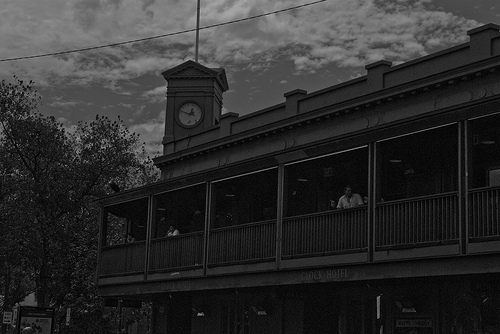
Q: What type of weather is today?
A: It is cloudy.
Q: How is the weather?
A: It is cloudy.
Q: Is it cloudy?
A: Yes, it is cloudy.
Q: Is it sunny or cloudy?
A: It is cloudy.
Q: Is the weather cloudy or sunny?
A: It is cloudy.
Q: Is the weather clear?
A: No, it is cloudy.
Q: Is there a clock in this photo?
A: Yes, there is a clock.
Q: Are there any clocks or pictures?
A: Yes, there is a clock.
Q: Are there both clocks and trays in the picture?
A: No, there is a clock but no trays.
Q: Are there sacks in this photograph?
A: No, there are no sacks.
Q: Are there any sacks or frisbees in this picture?
A: No, there are no sacks or frisbees.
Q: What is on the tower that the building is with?
A: The clock is on the tower.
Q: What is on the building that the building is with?
A: The clock is on the tower.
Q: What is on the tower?
A: The clock is on the tower.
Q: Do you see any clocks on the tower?
A: Yes, there is a clock on the tower.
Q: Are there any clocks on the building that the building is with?
A: Yes, there is a clock on the tower.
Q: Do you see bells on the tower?
A: No, there is a clock on the tower.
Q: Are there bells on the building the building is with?
A: No, there is a clock on the tower.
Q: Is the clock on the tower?
A: Yes, the clock is on the tower.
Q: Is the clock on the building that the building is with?
A: Yes, the clock is on the tower.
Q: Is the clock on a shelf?
A: No, the clock is on the tower.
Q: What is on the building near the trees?
A: The clock is on the building.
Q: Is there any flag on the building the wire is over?
A: No, there is a clock on the building.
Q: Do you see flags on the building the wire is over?
A: No, there is a clock on the building.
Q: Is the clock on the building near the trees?
A: Yes, the clock is on the building.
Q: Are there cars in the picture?
A: No, there are no cars.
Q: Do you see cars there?
A: No, there are no cars.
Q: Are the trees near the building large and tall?
A: Yes, the trees are large and tall.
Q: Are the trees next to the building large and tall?
A: Yes, the trees are large and tall.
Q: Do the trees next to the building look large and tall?
A: Yes, the trees are large and tall.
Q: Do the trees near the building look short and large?
A: No, the trees are large but tall.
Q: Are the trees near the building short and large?
A: No, the trees are large but tall.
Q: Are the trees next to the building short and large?
A: No, the trees are large but tall.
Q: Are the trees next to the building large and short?
A: No, the trees are large but tall.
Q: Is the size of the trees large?
A: Yes, the trees are large.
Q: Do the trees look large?
A: Yes, the trees are large.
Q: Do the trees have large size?
A: Yes, the trees are large.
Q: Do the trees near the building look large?
A: Yes, the trees are large.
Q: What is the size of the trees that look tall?
A: The trees are large.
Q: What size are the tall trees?
A: The trees are large.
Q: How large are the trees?
A: The trees are large.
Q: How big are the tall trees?
A: The trees are large.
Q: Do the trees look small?
A: No, the trees are large.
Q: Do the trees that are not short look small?
A: No, the trees are large.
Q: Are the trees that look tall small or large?
A: The trees are large.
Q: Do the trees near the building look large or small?
A: The trees are large.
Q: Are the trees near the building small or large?
A: The trees are large.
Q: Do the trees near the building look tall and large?
A: Yes, the trees are tall and large.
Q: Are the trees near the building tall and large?
A: Yes, the trees are tall and large.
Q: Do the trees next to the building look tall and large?
A: Yes, the trees are tall and large.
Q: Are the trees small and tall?
A: No, the trees are tall but large.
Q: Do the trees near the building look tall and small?
A: No, the trees are tall but large.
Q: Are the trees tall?
A: Yes, the trees are tall.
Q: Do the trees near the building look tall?
A: Yes, the trees are tall.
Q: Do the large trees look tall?
A: Yes, the trees are tall.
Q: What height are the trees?
A: The trees are tall.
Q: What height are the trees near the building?
A: The trees are tall.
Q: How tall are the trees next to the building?
A: The trees are tall.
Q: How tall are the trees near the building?
A: The trees are tall.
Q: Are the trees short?
A: No, the trees are tall.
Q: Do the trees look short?
A: No, the trees are tall.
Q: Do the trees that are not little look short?
A: No, the trees are tall.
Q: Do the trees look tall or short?
A: The trees are tall.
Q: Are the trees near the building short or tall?
A: The trees are tall.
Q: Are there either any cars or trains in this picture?
A: No, there are no cars or trains.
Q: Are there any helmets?
A: No, there are no helmets.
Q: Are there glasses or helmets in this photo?
A: No, there are no helmets or glasses.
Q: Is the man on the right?
A: Yes, the man is on the right of the image.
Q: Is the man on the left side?
A: No, the man is on the right of the image.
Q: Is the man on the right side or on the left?
A: The man is on the right of the image.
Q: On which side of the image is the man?
A: The man is on the right of the image.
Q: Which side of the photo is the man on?
A: The man is on the right of the image.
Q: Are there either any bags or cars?
A: No, there are no cars or bags.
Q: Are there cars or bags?
A: No, there are no cars or bags.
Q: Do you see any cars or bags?
A: No, there are no cars or bags.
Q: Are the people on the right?
A: Yes, the people are on the right of the image.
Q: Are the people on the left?
A: No, the people are on the right of the image.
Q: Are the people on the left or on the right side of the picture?
A: The people are on the right of the image.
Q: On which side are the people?
A: The people are on the right of the image.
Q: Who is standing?
A: The people are standing.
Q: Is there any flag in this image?
A: No, there are no flags.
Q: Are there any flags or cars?
A: No, there are no flags or cars.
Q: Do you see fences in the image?
A: Yes, there is a fence.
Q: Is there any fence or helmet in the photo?
A: Yes, there is a fence.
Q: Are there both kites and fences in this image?
A: No, there is a fence but no kites.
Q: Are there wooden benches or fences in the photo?
A: Yes, there is a wood fence.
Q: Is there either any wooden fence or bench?
A: Yes, there is a wood fence.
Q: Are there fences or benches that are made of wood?
A: Yes, the fence is made of wood.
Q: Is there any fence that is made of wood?
A: Yes, there is a fence that is made of wood.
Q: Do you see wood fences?
A: Yes, there is a fence that is made of wood.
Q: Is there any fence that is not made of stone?
A: Yes, there is a fence that is made of wood.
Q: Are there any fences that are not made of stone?
A: Yes, there is a fence that is made of wood.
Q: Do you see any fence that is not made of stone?
A: Yes, there is a fence that is made of wood.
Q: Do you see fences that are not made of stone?
A: Yes, there is a fence that is made of wood.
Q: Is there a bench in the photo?
A: No, there are no benches.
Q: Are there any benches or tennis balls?
A: No, there are no benches or tennis balls.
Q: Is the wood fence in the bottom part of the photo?
A: Yes, the fence is in the bottom of the image.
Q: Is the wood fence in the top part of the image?
A: No, the fence is in the bottom of the image.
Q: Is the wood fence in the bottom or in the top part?
A: The fence is in the bottom of the image.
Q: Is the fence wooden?
A: Yes, the fence is wooden.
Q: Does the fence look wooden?
A: Yes, the fence is wooden.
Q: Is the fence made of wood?
A: Yes, the fence is made of wood.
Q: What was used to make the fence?
A: The fence is made of wood.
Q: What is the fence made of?
A: The fence is made of wood.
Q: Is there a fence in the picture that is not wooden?
A: No, there is a fence but it is wooden.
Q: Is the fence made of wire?
A: No, the fence is made of wood.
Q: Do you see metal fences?
A: No, there is a fence but it is made of wood.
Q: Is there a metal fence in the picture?
A: No, there is a fence but it is made of wood.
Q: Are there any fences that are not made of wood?
A: No, there is a fence but it is made of wood.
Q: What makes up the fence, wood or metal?
A: The fence is made of wood.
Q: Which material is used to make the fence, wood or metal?
A: The fence is made of wood.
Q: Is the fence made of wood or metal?
A: The fence is made of wood.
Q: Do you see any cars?
A: No, there are no cars.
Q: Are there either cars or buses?
A: No, there are no cars or buses.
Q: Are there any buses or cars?
A: No, there are no cars or buses.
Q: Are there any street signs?
A: Yes, there is a street sign.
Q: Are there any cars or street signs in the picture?
A: Yes, there is a street sign.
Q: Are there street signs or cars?
A: Yes, there is a street sign.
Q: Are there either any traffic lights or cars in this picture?
A: No, there are no cars or traffic lights.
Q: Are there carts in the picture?
A: No, there are no carts.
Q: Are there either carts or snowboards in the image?
A: No, there are no carts or snowboards.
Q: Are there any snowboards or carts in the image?
A: No, there are no carts or snowboards.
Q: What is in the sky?
A: The wire is in the sky.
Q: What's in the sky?
A: The wire is in the sky.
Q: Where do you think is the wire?
A: The wire is in the sky.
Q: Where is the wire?
A: The wire is in the sky.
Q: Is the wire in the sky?
A: Yes, the wire is in the sky.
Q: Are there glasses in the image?
A: No, there are no glasses.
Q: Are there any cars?
A: No, there are no cars.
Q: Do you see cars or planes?
A: No, there are no cars or planes.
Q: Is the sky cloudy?
A: Yes, the sky is cloudy.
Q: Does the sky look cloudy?
A: Yes, the sky is cloudy.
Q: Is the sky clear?
A: No, the sky is cloudy.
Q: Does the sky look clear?
A: No, the sky is cloudy.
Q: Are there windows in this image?
A: Yes, there are windows.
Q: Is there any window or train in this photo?
A: Yes, there are windows.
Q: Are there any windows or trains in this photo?
A: Yes, there are windows.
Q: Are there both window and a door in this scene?
A: No, there are windows but no doors.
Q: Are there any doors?
A: No, there are no doors.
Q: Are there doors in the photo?
A: No, there are no doors.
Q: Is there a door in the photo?
A: No, there are no doors.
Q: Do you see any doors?
A: No, there are no doors.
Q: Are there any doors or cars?
A: No, there are no doors or cars.